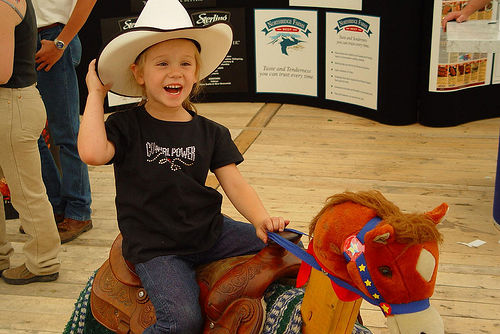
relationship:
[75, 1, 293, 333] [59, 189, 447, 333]
boy rides pony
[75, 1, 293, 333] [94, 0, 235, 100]
boy holds hat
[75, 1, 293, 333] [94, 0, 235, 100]
boy wears hat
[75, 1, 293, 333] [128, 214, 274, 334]
boy wears jeans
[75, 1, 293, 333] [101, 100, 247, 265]
boy wearing shirt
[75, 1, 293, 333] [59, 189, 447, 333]
boy riding pony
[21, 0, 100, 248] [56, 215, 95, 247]
man wears shoe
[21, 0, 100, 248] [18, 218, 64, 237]
man wears shoe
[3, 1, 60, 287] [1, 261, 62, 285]
woman wears shoe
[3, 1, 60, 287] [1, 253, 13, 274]
woman wears shoe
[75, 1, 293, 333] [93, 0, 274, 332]
boy wears cowboy outfit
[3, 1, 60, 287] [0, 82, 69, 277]
woman wears pants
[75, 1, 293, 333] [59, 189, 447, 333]
boy sitting on pony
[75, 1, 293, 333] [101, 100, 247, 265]
boy wears shirt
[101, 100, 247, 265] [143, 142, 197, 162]
shirt has cowgirl power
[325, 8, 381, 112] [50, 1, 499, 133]
promotional sign on wall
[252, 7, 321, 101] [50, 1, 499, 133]
promotional sign on wall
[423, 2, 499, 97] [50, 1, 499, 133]
sign on wall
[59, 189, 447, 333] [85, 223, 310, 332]
pony has saddle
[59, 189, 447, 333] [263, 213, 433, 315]
pony has reins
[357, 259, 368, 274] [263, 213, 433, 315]
star on reins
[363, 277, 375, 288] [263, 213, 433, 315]
star on reins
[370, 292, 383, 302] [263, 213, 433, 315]
star on reins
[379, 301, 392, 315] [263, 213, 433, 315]
star on reins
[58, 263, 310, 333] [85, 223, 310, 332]
blanket beneath saddle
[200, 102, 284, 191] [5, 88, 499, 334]
stripe on floor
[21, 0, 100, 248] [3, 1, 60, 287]
man next to woman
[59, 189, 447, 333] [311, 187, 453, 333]
pony has head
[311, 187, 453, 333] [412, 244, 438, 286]
head has a diamond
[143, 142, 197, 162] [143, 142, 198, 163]
cowgirl power says cowgirl power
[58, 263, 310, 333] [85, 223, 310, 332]
blanket under saddle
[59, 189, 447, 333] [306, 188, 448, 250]
pony has mane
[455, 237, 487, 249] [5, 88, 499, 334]
garbage on floor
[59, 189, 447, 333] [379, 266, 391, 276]
pony has eye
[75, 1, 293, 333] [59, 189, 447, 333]
boy on pony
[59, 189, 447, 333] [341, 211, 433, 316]
pony has bridle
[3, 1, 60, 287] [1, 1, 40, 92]
woman wears shirt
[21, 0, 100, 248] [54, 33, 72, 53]
man has wrist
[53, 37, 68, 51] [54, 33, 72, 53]
wristwatch on wrist